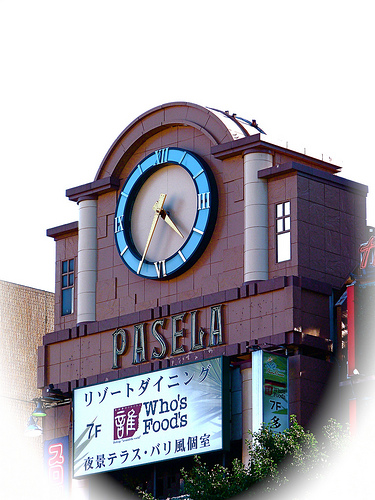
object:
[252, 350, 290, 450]
7f sign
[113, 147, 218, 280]
clock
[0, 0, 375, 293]
sky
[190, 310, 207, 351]
letter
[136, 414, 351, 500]
tree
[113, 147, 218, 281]
border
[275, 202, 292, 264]
window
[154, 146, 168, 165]
number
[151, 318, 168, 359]
letter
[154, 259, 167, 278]
number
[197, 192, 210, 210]
number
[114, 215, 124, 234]
number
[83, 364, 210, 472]
chinese writing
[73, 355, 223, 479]
sign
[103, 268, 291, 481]
sign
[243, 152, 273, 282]
column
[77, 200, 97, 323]
column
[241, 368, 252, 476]
column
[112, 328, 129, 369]
letter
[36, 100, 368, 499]
building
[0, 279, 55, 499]
building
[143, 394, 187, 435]
name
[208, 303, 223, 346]
letter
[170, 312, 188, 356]
letter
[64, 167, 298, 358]
wall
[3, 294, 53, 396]
wall